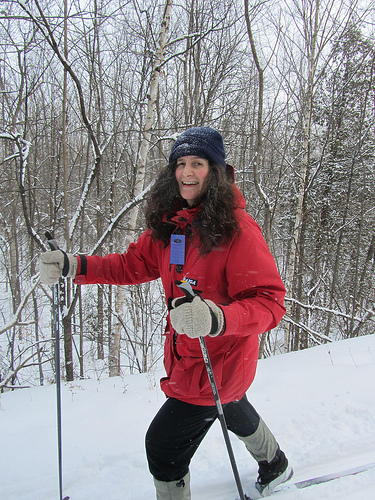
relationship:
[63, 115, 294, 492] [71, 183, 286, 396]
woman wears coat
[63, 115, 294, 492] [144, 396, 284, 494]
woman wears pants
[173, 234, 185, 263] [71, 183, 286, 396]
tag on coat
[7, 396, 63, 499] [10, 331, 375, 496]
snow on ground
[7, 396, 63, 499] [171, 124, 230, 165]
snow on cap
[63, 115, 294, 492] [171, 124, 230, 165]
woman wears cap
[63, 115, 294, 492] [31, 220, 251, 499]
woman holds poles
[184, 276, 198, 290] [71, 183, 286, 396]
label on coat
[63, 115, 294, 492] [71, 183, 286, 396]
woman in coat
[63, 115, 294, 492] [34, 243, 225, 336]
woman wears gloves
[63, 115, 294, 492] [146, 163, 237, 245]
woman has hair